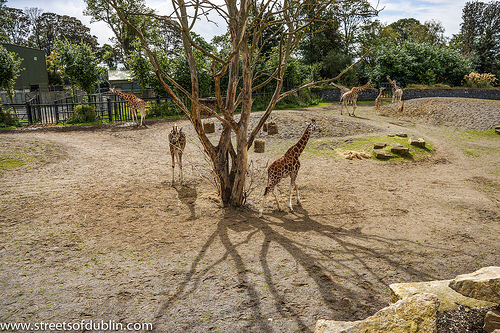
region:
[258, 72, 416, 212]
Giraffes standing inside enclosure.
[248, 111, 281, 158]
Food for giraffes hanging from tree.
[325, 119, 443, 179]
Grassy patch littered with stones.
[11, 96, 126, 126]
A fence surrounding enclosure.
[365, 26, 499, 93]
Trees growing off to side of enclosure.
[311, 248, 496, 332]
Huge rocks laying inside enclosure.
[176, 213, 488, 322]
Shadow of tree and giraffe on ground.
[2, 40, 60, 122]
Edge of green building outside enclosure.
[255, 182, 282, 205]
Black tip of giraffe's tail.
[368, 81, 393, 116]
Baby giraffe next to adult giraffes.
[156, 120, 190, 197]
A young giraffe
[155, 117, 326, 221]
Two young giraffes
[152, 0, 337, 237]
Two young giraffes walking around a tree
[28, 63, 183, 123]
A giraffe standing behind a fence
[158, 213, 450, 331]
The shadow of a tree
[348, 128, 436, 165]
A rocky patch of grass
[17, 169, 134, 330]
A patch of dirt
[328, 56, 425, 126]
A group of giraffes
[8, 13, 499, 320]
Giraffes in a zoo exhibit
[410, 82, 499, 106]
A stone wall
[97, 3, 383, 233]
a tree in the middle of the habitat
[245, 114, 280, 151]
food hanging from the tree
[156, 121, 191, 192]
a small giraffe looking straight ahead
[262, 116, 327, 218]
the small giraffe closest to the tree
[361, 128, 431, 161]
large rocks on the grass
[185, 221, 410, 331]
the shadow made by the tree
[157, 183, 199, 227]
the giraffe's shadow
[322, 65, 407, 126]
many giraffes in the distance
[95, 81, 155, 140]
one giraffe alone by the black fence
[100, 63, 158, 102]
a small building behind the giraffe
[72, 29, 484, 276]
giraffes in an enclosure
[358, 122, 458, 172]
rocks on grass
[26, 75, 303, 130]
giraffe next to metal fence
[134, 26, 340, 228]
two giraffes next to a tree with no leaves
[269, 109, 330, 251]
young giraffe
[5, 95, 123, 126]
metal fence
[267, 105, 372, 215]
giraffe is white with brown spots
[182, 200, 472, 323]
shadow on ground from tree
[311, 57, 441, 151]
cluster of giraffes in a pen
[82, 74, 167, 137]
giraffe leaning over fence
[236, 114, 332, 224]
Giraffe next to a tree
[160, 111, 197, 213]
Giraffe neck is low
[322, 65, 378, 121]
Giraffe walk in the pen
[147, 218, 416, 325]
Shadow of tree on the ground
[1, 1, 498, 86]
Trees in the background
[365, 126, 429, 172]
Stones on green grass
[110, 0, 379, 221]
Tree in the center of giraffe pen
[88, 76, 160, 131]
Giraffe next to fence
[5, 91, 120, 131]
Fence of giraffe pen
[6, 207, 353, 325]
Soil in the grownd